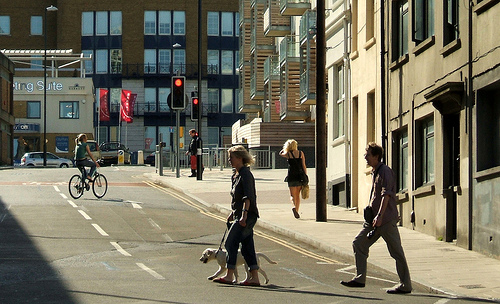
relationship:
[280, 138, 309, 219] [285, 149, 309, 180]
woman with dress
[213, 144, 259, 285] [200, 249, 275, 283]
woman leading dog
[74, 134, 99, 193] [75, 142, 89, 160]
woman with shirt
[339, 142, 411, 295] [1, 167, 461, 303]
man walking across street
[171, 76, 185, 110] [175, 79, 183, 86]
light showing red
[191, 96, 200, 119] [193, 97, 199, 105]
light showing red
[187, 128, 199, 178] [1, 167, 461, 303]
man standing by road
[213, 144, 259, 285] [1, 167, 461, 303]
woman walking down street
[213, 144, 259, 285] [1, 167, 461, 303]
woman crossing street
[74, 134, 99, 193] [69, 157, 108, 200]
woman riding bike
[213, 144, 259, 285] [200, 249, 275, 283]
woman walking dog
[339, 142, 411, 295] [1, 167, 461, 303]
person crossing street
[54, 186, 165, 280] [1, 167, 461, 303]
line in street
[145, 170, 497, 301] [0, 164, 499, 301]
sidewalk goes up hill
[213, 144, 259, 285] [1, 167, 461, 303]
person crossing street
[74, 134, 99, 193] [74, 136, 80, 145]
woman wearing ponytail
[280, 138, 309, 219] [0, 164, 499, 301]
woman walking hill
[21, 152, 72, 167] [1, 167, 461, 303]
car on road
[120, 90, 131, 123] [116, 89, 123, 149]
flag on pole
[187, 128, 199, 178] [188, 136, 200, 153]
man wearing jacket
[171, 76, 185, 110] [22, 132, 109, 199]
light for traffic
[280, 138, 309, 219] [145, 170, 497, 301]
woman walking on side walk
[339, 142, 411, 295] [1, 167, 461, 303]
man crossing street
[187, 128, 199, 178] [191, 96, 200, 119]
man standing at light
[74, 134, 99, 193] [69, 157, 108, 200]
woman on bicycle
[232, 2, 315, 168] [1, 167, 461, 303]
building on side of street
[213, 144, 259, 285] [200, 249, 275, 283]
woman with dog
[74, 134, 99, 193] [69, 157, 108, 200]
woman on bike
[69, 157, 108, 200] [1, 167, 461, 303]
bicycle on street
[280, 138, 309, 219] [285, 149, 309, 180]
woman in dress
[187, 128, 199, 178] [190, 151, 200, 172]
man in pants